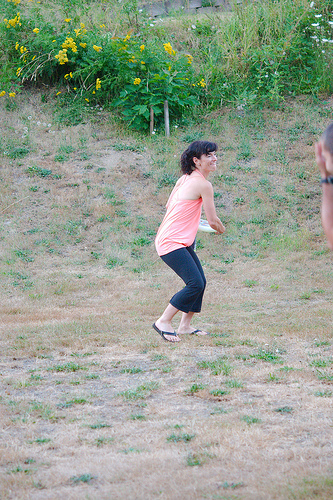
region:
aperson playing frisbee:
[122, 117, 230, 361]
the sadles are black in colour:
[146, 309, 184, 353]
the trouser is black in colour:
[161, 241, 207, 310]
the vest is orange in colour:
[172, 167, 207, 254]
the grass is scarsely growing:
[36, 359, 148, 434]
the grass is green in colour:
[59, 399, 87, 409]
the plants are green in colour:
[61, 13, 184, 103]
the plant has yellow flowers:
[44, 15, 190, 93]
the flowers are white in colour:
[292, 8, 332, 60]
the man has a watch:
[315, 162, 332, 184]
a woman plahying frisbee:
[87, 126, 330, 345]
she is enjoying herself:
[124, 134, 252, 355]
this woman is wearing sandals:
[135, 293, 224, 362]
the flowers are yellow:
[7, 15, 214, 102]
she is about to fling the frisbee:
[177, 195, 238, 245]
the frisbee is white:
[196, 216, 228, 238]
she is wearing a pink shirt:
[144, 183, 212, 254]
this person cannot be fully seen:
[287, 118, 330, 247]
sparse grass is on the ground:
[26, 140, 290, 338]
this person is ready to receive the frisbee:
[289, 108, 330, 265]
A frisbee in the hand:
[201, 225, 208, 230]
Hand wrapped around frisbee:
[214, 230, 220, 233]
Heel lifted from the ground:
[153, 326, 155, 327]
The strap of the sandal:
[168, 332, 173, 334]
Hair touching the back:
[186, 170, 191, 174]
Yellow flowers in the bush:
[66, 40, 73, 45]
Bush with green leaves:
[145, 90, 162, 98]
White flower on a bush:
[313, 24, 318, 26]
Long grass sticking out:
[237, 21, 250, 55]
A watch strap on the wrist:
[322, 180, 330, 181]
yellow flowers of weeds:
[3, 4, 203, 120]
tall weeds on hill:
[5, 4, 328, 125]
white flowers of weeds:
[310, 5, 329, 57]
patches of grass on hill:
[5, 100, 328, 267]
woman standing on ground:
[152, 138, 224, 340]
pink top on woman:
[154, 173, 210, 256]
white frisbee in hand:
[197, 218, 224, 233]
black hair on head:
[179, 139, 218, 174]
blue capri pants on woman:
[161, 245, 206, 313]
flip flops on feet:
[153, 320, 205, 342]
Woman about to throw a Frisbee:
[153, 140, 225, 343]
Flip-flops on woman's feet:
[152, 317, 207, 343]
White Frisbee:
[198, 217, 214, 234]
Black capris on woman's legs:
[159, 236, 207, 316]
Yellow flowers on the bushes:
[2, 0, 209, 134]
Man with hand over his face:
[315, 118, 332, 255]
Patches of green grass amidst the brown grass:
[0, 113, 330, 497]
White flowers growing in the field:
[306, 0, 331, 93]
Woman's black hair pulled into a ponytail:
[180, 139, 219, 178]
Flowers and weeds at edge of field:
[3, 0, 330, 152]